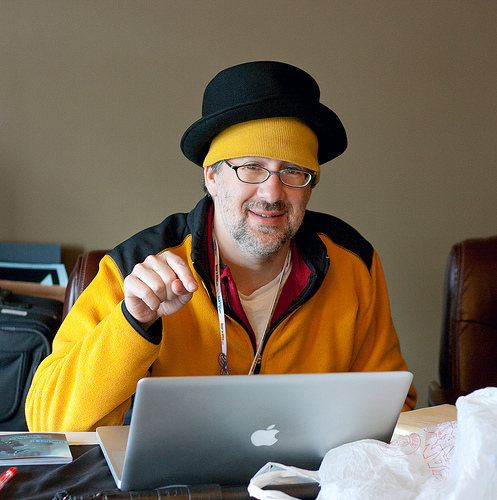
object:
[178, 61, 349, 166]
hat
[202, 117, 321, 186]
hat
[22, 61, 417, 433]
man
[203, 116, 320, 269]
head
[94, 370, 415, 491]
laptop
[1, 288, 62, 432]
bag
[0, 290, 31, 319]
handle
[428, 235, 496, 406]
chair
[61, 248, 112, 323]
chair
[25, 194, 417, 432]
sweater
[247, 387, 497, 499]
grocery bag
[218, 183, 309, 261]
beard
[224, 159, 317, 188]
eyeglasses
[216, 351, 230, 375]
pin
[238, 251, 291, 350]
under shirt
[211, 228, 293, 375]
lanyard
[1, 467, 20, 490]
pen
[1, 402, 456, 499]
table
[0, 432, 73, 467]
book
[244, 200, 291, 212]
moustache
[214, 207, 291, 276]
neck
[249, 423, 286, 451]
apple icon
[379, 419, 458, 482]
writing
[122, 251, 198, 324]
hand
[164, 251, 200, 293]
finger